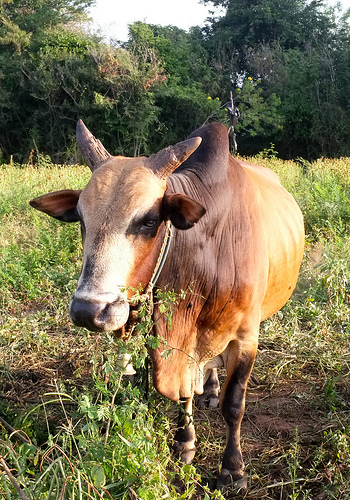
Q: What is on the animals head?
A: Horns.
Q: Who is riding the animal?
A: No one.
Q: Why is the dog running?
A: No dog.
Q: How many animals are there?
A: One.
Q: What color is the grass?
A: Green.